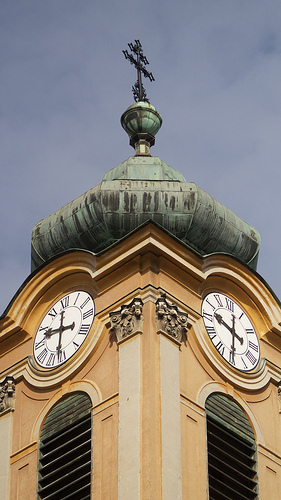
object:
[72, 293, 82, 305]
roman numeral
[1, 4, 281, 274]
sky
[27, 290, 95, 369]
face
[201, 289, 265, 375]
clock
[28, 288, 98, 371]
clock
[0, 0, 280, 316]
clouds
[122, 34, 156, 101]
weather vane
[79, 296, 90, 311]
2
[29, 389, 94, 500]
window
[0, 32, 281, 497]
building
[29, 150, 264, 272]
structure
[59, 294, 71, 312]
roman numeral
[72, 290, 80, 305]
roman numeral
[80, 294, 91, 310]
roman numeral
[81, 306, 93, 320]
roman numeral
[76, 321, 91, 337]
roman numeral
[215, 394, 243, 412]
wood slats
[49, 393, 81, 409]
wood slats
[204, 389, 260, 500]
window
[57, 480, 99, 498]
vents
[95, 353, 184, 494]
wall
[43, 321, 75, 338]
hour hand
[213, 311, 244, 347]
hour hand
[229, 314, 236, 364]
minute hand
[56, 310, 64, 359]
minute hand